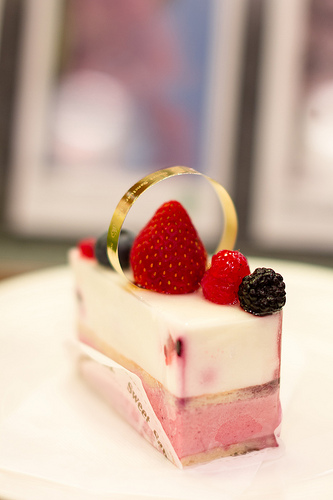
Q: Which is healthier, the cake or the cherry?
A: The cherry is healthier than the cake.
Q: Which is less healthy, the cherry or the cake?
A: The cake is less healthy than the cherry.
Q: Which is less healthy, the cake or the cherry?
A: The cake is less healthy than the cherry.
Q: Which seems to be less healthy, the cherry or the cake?
A: The cake is less healthy than the cherry.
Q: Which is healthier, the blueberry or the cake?
A: The blueberry is healthier than the cake.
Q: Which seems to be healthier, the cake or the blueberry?
A: The blueberry is healthier than the cake.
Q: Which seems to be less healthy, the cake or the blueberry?
A: The cake is less healthy than the blueberry.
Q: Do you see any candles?
A: No, there are no candles.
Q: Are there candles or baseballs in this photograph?
A: No, there are no candles or baseballs.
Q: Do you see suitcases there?
A: No, there are no suitcases.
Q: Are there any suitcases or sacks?
A: No, there are no suitcases or sacks.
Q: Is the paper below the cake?
A: Yes, the paper is below the cake.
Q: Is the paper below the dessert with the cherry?
A: Yes, the paper is below the cake.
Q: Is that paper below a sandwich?
A: No, the paper is below the cake.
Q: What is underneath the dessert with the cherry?
A: The paper is underneath the cake.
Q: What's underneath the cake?
A: The paper is underneath the cake.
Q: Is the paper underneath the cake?
A: Yes, the paper is underneath the cake.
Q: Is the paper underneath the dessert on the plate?
A: Yes, the paper is underneath the cake.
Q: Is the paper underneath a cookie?
A: No, the paper is underneath the cake.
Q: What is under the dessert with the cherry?
A: The paper is under the cake.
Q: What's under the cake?
A: The paper is under the cake.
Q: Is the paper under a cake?
A: Yes, the paper is under a cake.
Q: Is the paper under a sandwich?
A: No, the paper is under a cake.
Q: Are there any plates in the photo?
A: Yes, there is a plate.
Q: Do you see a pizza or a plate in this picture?
A: Yes, there is a plate.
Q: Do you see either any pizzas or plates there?
A: Yes, there is a plate.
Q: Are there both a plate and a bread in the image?
A: No, there is a plate but no breads.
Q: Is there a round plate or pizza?
A: Yes, there is a round plate.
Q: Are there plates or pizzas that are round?
A: Yes, the plate is round.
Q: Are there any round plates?
A: Yes, there is a round plate.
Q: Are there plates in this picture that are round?
A: Yes, there is a plate that is round.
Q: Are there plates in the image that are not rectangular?
A: Yes, there is a round plate.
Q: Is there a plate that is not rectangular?
A: Yes, there is a round plate.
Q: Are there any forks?
A: No, there are no forks.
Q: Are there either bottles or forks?
A: No, there are no forks or bottles.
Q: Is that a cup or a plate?
A: That is a plate.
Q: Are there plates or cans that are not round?
A: No, there is a plate but it is round.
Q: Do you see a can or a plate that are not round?
A: No, there is a plate but it is round.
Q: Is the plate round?
A: Yes, the plate is round.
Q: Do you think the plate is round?
A: Yes, the plate is round.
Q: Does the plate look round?
A: Yes, the plate is round.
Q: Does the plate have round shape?
A: Yes, the plate is round.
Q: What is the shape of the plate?
A: The plate is round.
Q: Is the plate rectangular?
A: No, the plate is round.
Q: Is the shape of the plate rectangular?
A: No, the plate is round.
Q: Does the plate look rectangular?
A: No, the plate is round.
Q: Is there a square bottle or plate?
A: No, there is a plate but it is round.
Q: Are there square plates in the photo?
A: No, there is a plate but it is round.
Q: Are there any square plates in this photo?
A: No, there is a plate but it is round.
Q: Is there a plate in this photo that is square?
A: No, there is a plate but it is round.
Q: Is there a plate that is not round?
A: No, there is a plate but it is round.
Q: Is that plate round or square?
A: The plate is round.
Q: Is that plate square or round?
A: The plate is round.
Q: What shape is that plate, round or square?
A: The plate is round.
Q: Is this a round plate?
A: Yes, this is a round plate.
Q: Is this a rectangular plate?
A: No, this is a round plate.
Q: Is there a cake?
A: Yes, there is a cake.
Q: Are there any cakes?
A: Yes, there is a cake.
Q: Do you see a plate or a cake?
A: Yes, there is a cake.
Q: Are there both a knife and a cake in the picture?
A: No, there is a cake but no knives.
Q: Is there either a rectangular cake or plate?
A: Yes, there is a rectangular cake.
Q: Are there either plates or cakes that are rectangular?
A: Yes, the cake is rectangular.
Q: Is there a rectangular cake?
A: Yes, there is a rectangular cake.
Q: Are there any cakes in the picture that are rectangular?
A: Yes, there is a cake that is rectangular.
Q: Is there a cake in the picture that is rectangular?
A: Yes, there is a cake that is rectangular.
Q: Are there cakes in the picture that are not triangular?
A: Yes, there is a rectangular cake.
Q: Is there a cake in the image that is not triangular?
A: Yes, there is a rectangular cake.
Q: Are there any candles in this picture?
A: No, there are no candles.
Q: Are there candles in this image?
A: No, there are no candles.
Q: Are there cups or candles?
A: No, there are no candles or cups.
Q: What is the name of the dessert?
A: The dessert is a cake.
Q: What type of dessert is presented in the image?
A: The dessert is a cake.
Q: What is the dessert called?
A: The dessert is a cake.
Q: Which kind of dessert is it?
A: The dessert is a cake.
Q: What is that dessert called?
A: That is a cake.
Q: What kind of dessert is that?
A: That is a cake.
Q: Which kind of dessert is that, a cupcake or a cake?
A: That is a cake.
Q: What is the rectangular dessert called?
A: The dessert is a cake.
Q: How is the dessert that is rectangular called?
A: The dessert is a cake.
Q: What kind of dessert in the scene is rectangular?
A: The dessert is a cake.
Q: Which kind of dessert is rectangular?
A: The dessert is a cake.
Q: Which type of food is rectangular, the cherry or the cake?
A: The cake is rectangular.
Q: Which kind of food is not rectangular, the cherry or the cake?
A: The cherry is not rectangular.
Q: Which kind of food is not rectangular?
A: The food is a cherry.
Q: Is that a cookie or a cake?
A: That is a cake.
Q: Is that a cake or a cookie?
A: That is a cake.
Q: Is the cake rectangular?
A: Yes, the cake is rectangular.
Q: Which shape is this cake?
A: The cake is rectangular.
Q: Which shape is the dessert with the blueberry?
A: The cake is rectangular.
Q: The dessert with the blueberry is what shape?
A: The cake is rectangular.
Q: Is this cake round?
A: No, the cake is rectangular.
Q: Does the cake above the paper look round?
A: No, the cake is rectangular.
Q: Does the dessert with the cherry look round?
A: No, the cake is rectangular.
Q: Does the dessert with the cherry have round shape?
A: No, the cake is rectangular.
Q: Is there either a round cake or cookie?
A: No, there is a cake but it is rectangular.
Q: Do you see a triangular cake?
A: No, there is a cake but it is rectangular.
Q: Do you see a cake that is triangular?
A: No, there is a cake but it is rectangular.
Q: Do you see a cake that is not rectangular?
A: No, there is a cake but it is rectangular.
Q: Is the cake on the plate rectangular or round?
A: The cake is rectangular.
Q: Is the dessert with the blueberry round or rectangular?
A: The cake is rectangular.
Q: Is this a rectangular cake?
A: Yes, this is a rectangular cake.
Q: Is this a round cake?
A: No, this is a rectangular cake.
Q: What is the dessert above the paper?
A: The dessert is a cake.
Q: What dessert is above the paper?
A: The dessert is a cake.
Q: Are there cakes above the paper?
A: Yes, there is a cake above the paper.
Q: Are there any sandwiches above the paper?
A: No, there is a cake above the paper.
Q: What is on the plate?
A: The cake is on the plate.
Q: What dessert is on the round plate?
A: The dessert is a cake.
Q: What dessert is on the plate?
A: The dessert is a cake.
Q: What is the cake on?
A: The cake is on the plate.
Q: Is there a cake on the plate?
A: Yes, there is a cake on the plate.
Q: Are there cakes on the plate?
A: Yes, there is a cake on the plate.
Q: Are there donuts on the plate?
A: No, there is a cake on the plate.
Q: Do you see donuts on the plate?
A: No, there is a cake on the plate.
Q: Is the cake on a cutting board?
A: No, the cake is on the plate.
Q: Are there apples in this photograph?
A: No, there are no apples.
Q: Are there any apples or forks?
A: No, there are no apples or forks.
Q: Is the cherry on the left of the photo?
A: Yes, the cherry is on the left of the image.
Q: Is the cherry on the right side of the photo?
A: No, the cherry is on the left of the image.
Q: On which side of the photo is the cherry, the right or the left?
A: The cherry is on the left of the image.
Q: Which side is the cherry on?
A: The cherry is on the left of the image.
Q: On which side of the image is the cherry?
A: The cherry is on the left of the image.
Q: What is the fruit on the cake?
A: The fruit is a cherry.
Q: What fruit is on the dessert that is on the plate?
A: The fruit is a cherry.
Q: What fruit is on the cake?
A: The fruit is a cherry.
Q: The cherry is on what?
A: The cherry is on the cake.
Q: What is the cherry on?
A: The cherry is on the cake.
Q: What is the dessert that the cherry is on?
A: The dessert is a cake.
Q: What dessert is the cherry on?
A: The cherry is on the cake.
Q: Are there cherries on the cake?
A: Yes, there is a cherry on the cake.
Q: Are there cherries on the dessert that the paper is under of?
A: Yes, there is a cherry on the cake.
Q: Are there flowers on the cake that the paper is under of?
A: No, there is a cherry on the cake.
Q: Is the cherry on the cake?
A: Yes, the cherry is on the cake.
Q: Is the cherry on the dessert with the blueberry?
A: Yes, the cherry is on the cake.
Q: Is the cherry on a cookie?
A: No, the cherry is on the cake.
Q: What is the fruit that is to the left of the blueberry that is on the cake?
A: The fruit is a cherry.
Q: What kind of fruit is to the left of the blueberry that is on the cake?
A: The fruit is a cherry.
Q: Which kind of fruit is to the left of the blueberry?
A: The fruit is a cherry.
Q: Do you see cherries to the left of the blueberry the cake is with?
A: Yes, there is a cherry to the left of the blueberry.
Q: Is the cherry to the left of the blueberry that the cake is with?
A: Yes, the cherry is to the left of the blueberry.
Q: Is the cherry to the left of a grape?
A: No, the cherry is to the left of the blueberry.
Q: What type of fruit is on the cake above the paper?
A: The fruit is a blueberry.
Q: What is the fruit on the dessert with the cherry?
A: The fruit is a blueberry.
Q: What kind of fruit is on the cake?
A: The fruit is a blueberry.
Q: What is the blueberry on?
A: The blueberry is on the cake.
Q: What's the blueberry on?
A: The blueberry is on the cake.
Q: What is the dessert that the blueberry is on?
A: The dessert is a cake.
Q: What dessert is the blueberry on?
A: The blueberry is on the cake.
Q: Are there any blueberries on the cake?
A: Yes, there is a blueberry on the cake.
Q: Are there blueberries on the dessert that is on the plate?
A: Yes, there is a blueberry on the cake.